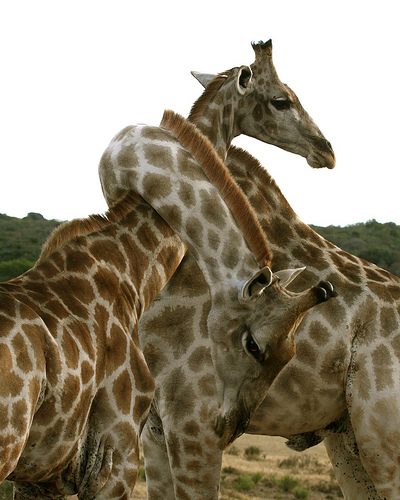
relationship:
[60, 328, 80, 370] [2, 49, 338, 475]
spot on giraffe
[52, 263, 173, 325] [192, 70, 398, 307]
brown spot on giraffe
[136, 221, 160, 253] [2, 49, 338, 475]
spot on giraffe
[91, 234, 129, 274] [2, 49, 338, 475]
brown spot on giraffe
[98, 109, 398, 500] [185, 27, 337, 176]
giraffe next to giraffe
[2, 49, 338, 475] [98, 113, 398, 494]
giraffe next to giraffe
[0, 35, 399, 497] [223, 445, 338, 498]
giraffes standing on sand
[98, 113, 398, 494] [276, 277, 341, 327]
giraffe has horns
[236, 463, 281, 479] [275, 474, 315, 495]
ground patched with grass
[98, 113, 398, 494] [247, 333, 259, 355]
giraffe has eye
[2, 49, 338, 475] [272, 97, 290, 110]
giraffe has eye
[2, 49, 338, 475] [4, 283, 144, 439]
giraffe has spots